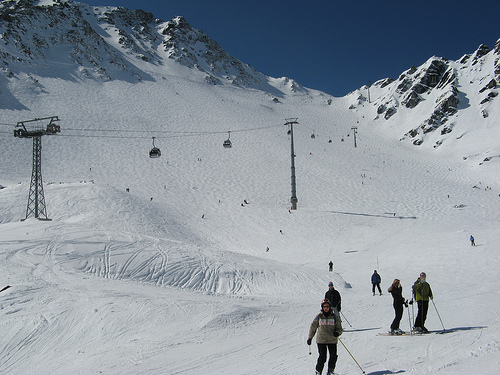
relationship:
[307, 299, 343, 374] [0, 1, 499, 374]
person on top of snow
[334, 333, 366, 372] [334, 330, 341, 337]
ski pole within a hand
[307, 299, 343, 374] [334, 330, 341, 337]
person has hand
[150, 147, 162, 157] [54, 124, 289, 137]
ski lift chair hanging on wire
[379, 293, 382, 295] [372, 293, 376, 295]
ski next to ski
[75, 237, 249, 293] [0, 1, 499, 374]
ski tracks on top of snow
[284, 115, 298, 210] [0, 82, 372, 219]
pole supporting ski lift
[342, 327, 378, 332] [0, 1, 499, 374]
shadow on top of snow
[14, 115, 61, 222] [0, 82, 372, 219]
tower supporting ski lift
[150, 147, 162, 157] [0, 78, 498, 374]
ski lift chair on ski slope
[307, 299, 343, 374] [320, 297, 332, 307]
person wearing helmet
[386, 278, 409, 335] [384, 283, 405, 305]
skier wearing jacket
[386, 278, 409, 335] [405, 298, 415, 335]
skier has ski pole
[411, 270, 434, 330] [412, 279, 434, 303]
skier wearing jacket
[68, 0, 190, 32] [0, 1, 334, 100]
top of mountain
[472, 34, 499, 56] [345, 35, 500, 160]
top of mountain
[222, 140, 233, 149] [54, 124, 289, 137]
ski lift chair connected to wire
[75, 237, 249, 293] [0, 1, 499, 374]
ski tracks etched in snow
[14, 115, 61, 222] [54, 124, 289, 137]
tower supports wire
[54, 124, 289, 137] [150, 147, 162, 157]
wire for ski lift chair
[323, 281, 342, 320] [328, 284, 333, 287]
skier wearing goggles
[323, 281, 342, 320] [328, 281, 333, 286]
skier wearing hat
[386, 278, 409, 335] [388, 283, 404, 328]
skier wearing black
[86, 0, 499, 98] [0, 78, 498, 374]
sky above ski slope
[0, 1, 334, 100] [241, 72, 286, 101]
mountain casts shadow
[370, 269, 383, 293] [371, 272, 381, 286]
skier wearing jacket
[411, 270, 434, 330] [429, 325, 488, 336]
skier casting shadow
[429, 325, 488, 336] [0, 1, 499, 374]
shadow on top of snow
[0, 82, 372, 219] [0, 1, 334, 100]
ski lift on mountain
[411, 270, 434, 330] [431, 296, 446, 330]
skier holding ski pole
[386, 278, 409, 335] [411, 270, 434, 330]
skier skiing next to skier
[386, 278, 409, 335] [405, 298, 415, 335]
skier holding ski pole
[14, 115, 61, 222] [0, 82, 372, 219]
tower for ski lift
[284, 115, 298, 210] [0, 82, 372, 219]
pole for ski lift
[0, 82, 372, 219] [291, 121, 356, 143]
ski lift has wire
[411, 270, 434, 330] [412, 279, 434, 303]
skier has jacket